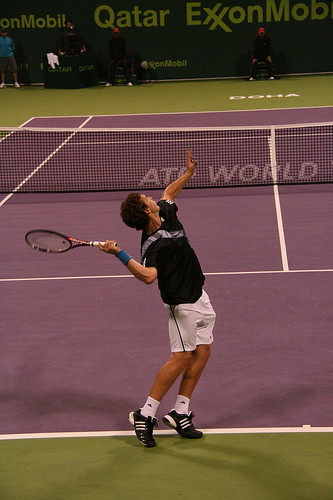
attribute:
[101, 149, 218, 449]
player — professional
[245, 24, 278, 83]
judge — watching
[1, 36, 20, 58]
t-shirt — blue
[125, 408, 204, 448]
sneakers — adidas, black, white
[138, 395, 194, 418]
socks — adidas, white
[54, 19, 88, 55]
camera man — standing, filming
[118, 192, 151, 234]
hair — brown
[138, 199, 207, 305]
shirt — black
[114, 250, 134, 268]
wrist band — blue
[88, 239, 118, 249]
grip — white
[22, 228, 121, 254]
racket — black, red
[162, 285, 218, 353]
pants — white, black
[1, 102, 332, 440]
court — purple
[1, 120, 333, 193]
net — black, white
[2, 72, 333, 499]
court — grey, green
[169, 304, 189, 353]
stripe — black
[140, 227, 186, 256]
accent — gray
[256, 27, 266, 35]
cap — orange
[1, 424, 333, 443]
line — white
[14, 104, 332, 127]
line — white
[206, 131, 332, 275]
line — white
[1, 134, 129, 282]
line — white